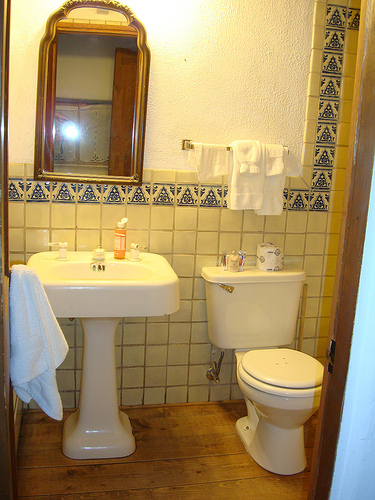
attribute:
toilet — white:
[198, 252, 326, 477]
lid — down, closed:
[238, 343, 329, 399]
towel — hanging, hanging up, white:
[229, 140, 263, 213]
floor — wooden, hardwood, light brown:
[19, 399, 321, 497]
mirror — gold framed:
[32, 2, 155, 189]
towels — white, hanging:
[226, 137, 291, 220]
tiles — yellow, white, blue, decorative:
[307, 8, 358, 215]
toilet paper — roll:
[253, 242, 289, 273]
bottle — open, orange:
[104, 215, 133, 259]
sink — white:
[28, 252, 181, 318]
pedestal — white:
[61, 320, 135, 459]